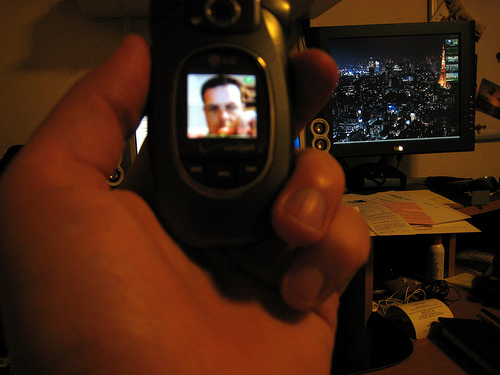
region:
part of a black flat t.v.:
[310, 20, 478, 155]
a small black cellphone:
[145, 2, 300, 253]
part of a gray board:
[421, 0, 496, 145]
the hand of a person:
[1, 30, 371, 371]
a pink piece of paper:
[385, 200, 435, 225]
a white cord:
[380, 280, 425, 312]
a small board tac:
[473, 121, 488, 128]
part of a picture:
[477, 77, 498, 122]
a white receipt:
[390, 297, 457, 341]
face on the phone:
[178, 71, 256, 153]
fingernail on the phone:
[271, 178, 337, 238]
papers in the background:
[363, 181, 441, 248]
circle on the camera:
[201, 3, 248, 46]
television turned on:
[341, 16, 479, 165]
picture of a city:
[368, 58, 416, 114]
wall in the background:
[16, 25, 69, 83]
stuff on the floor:
[377, 261, 477, 348]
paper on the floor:
[406, 292, 449, 335]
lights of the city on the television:
[343, 39, 423, 122]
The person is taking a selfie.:
[97, 25, 353, 272]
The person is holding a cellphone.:
[56, 26, 373, 316]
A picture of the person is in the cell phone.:
[184, 64, 262, 152]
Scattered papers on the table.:
[367, 173, 474, 238]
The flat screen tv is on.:
[324, 16, 499, 167]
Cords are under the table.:
[388, 268, 457, 300]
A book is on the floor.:
[428, 307, 497, 362]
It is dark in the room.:
[44, 11, 450, 301]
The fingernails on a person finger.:
[290, 178, 327, 225]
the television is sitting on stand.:
[314, 11, 472, 237]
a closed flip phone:
[136, 5, 288, 261]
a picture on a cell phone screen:
[176, 68, 260, 133]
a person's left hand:
[27, 73, 344, 352]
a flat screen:
[305, 32, 479, 150]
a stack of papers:
[351, 182, 461, 232]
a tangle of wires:
[372, 287, 459, 309]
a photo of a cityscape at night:
[347, 63, 442, 128]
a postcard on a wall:
[482, 82, 499, 110]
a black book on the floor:
[440, 316, 490, 373]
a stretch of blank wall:
[1, 8, 111, 80]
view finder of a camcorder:
[298, 13, 488, 173]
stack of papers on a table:
[335, 174, 487, 246]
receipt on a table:
[386, 291, 465, 350]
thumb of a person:
[5, 28, 167, 238]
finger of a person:
[249, 141, 357, 259]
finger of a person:
[259, 200, 377, 320]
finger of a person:
[257, 40, 342, 143]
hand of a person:
[2, 33, 387, 374]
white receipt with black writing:
[386, 290, 456, 345]